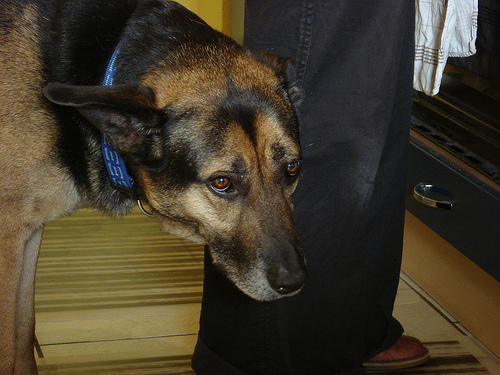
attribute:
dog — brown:
[18, 43, 288, 323]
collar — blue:
[87, 18, 147, 164]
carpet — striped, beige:
[81, 249, 191, 348]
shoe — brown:
[369, 303, 433, 373]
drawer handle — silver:
[404, 176, 457, 236]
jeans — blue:
[268, 10, 399, 348]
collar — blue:
[88, 44, 136, 223]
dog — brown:
[0, 7, 327, 323]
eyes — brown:
[200, 152, 304, 219]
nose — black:
[263, 259, 310, 296]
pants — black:
[248, 4, 411, 326]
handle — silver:
[405, 178, 454, 215]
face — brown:
[154, 72, 327, 308]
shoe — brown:
[368, 324, 433, 374]